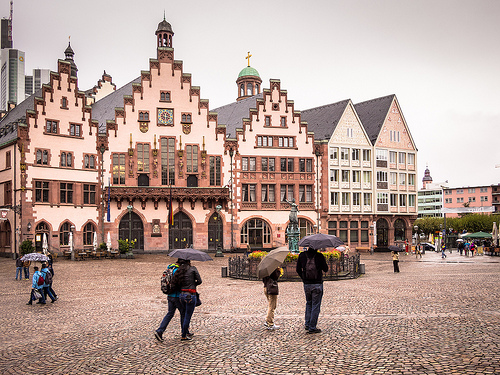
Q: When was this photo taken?
A: Daytime.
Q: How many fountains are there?
A: One.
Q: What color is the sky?
A: Grey.